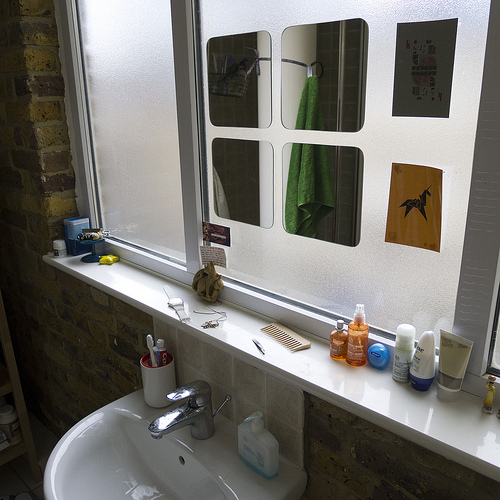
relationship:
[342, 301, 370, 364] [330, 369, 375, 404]
spray bottle on counter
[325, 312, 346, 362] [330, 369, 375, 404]
spray bottle on counter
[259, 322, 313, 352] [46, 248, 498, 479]
comb on counter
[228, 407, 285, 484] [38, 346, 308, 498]
container on sink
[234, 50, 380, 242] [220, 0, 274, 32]
squares on glass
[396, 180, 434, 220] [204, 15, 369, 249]
unicorn on mirrors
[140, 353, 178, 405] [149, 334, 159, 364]
cup with toothbrush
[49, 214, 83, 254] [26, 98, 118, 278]
containers on corner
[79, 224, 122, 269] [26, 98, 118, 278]
knickknackkers on corner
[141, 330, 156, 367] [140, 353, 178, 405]
toothbrush in cup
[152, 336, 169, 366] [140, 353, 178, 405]
toothpaste in cup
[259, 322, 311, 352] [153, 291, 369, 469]
comb on shelf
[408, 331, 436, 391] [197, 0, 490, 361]
bottle next window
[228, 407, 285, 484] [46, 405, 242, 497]
container next sink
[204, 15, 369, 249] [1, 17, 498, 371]
mirrors on wall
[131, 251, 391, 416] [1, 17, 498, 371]
white counter on wall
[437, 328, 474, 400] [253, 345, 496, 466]
toiletry on counter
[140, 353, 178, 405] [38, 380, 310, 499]
cup on sink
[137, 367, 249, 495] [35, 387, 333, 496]
faucet over sink